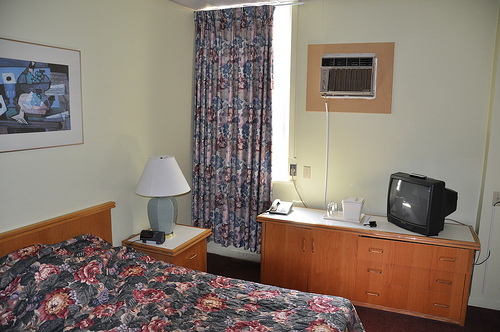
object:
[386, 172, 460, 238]
tv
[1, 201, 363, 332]
bed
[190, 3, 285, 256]
curtain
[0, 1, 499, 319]
wall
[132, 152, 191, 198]
lamp shade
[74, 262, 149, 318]
blanket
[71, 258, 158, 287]
flowers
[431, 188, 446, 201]
ground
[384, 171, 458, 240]
tv stand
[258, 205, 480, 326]
dresser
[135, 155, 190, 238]
lamp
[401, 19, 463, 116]
wall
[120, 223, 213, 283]
night stand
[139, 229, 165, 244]
alarm clock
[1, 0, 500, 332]
hotel room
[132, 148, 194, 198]
shade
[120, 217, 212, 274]
table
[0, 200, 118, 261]
cot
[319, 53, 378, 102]
ac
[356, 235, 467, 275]
drawer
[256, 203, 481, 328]
stand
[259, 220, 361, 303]
cabinet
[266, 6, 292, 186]
window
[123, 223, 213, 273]
stand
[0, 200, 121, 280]
headboard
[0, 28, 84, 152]
painting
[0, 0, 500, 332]
room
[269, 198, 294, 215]
phone